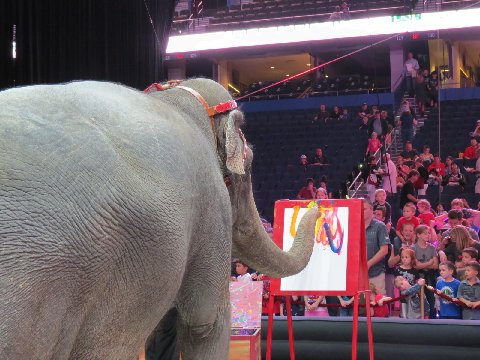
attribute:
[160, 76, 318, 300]
elephant — painting, gray, wrinkled, rough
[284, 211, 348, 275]
paper — white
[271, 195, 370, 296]
easel — red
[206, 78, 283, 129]
harness — red, pink, brown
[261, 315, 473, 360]
fence — gray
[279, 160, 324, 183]
seats — black, blue, empty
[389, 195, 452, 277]
kids — watching, sitting, amazed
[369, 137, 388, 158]
shirt — pink, blue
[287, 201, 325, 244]
paint — yellow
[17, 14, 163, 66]
curtain — black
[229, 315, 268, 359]
box — wooden, open, pink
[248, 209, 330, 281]
trunks — painting, long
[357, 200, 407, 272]
adults — watching, amazed